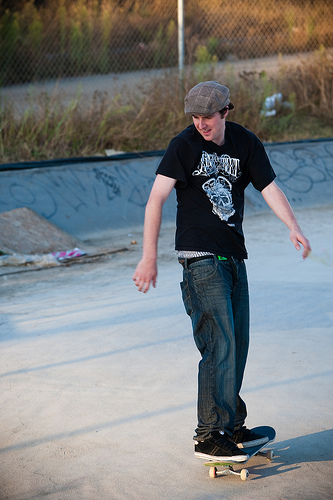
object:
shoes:
[192, 413, 267, 462]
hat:
[183, 79, 234, 121]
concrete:
[0, 132, 333, 252]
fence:
[2, 0, 332, 112]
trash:
[257, 89, 283, 122]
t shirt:
[155, 121, 277, 260]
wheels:
[206, 448, 276, 483]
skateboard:
[193, 422, 275, 479]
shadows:
[246, 427, 332, 480]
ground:
[0, 202, 332, 496]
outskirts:
[157, 122, 278, 259]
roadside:
[0, 48, 329, 178]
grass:
[1, 43, 332, 160]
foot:
[194, 430, 250, 465]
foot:
[224, 423, 268, 448]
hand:
[130, 252, 160, 293]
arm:
[252, 148, 313, 261]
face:
[191, 112, 226, 141]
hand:
[289, 226, 312, 259]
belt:
[177, 250, 248, 265]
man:
[130, 79, 313, 460]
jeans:
[178, 246, 250, 437]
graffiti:
[3, 136, 331, 227]